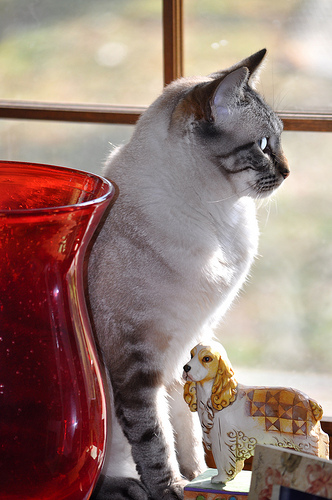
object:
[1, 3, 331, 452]
window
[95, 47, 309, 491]
cat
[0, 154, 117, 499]
vase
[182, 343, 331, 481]
toy